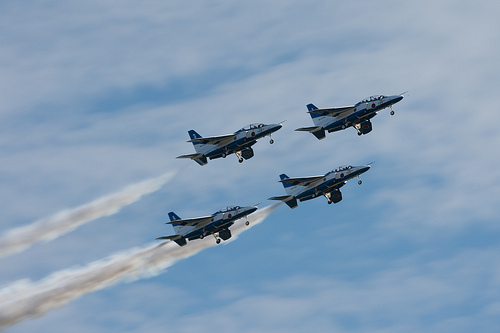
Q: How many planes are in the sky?
A: 4.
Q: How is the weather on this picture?
A: Cloudy.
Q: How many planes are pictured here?
A: Four.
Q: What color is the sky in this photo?
A: Blue.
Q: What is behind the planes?
A: Smoke trails.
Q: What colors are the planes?
A: Blue and White.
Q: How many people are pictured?
A: Zero.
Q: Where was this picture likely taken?
A: An Air Show.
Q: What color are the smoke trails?
A: White.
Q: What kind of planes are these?
A: Fighter planes.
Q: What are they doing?
A: Flying.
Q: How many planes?
A: 4.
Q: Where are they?
A: Air.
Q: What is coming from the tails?
A: Smoke.